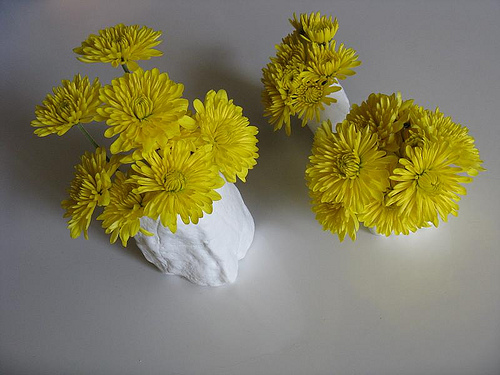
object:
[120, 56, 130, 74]
stem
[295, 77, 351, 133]
vase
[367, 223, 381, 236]
vase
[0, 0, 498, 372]
base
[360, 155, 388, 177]
petals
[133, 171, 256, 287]
container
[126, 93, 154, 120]
middle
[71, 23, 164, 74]
yellow flower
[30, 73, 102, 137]
yellow flower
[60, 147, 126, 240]
yellow flower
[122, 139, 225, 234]
yellow flower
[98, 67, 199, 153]
yellow flower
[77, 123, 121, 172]
stem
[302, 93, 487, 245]
flower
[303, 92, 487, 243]
group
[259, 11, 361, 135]
group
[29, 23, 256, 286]
group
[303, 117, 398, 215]
yellow flowers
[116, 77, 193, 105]
petals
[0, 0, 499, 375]
table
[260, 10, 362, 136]
flowers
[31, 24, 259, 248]
flowers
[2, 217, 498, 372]
background